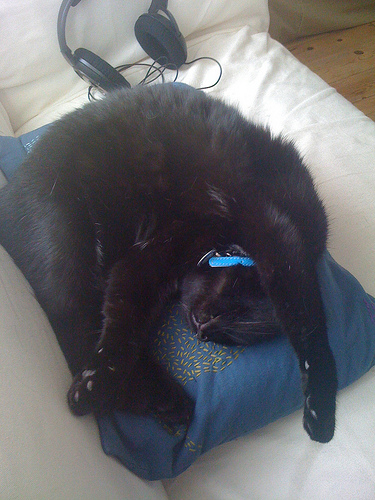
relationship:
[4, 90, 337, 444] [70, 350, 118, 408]
cat has a paw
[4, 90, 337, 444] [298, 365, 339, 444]
cat has a paw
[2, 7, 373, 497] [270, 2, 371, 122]
couch by floor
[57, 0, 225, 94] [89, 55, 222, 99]
headphones has wires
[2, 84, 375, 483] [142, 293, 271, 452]
pillow has pattern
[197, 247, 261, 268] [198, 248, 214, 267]
collar has tag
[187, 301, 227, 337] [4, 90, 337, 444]
mouth of cat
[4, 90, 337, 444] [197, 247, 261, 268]
cat has a collar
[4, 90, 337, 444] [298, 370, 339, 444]
cat has paw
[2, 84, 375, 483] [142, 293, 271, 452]
pillow has a pattern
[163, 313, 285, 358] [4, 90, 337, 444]
whiskars of a cat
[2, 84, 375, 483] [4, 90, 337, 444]
pillow under a cat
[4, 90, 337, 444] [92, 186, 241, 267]
cat has white hairs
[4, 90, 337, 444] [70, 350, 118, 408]
cat has paw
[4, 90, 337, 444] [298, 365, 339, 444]
cat has paw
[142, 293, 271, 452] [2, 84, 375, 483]
pattern on pillow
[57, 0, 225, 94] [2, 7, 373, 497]
headphones on top of couch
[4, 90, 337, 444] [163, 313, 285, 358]
cat has whiskars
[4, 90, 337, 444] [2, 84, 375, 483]
cat on top of pillow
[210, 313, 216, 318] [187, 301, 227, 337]
tooth of mouth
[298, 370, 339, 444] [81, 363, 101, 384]
paw have pads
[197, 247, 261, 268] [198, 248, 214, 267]
collar has a tag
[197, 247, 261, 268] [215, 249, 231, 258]
collar has buckle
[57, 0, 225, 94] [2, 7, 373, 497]
headphones on couch